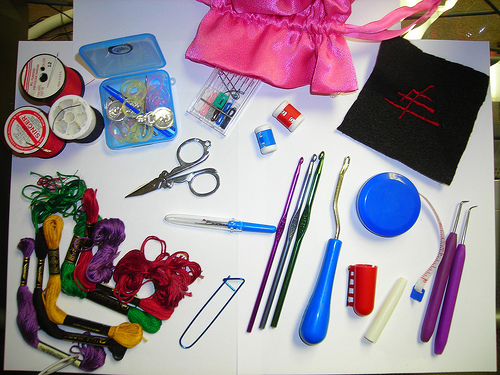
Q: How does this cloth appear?
A: Pink with ties.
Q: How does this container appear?
A: Blue.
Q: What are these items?
A: Cross stick flosses.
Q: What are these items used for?
A: Sewing.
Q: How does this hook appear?
A: Blue.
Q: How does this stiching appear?
A: Red.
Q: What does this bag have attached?
A: Drawstring.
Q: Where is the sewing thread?
A: Upper left.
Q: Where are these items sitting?
A: On a table.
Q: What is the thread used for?
A: Sewing.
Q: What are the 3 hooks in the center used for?
A: Crocheting.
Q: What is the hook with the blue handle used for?
A: Latchhook.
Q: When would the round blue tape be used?
A: Measuring.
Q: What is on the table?
A: Crafting supplies.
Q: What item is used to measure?
A: The tape measure.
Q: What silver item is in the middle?
A: Scissors.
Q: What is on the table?
A: Craft supplies.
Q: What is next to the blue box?
A: Thread.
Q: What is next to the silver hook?
A: Crochet hooks.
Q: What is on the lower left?
A: String.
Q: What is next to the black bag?
A: A pink dress.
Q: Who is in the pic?
A: No one.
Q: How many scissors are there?
A: 1.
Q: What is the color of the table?
A: White.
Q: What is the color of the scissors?
A: Silver.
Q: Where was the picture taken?
A: In the dentist office.